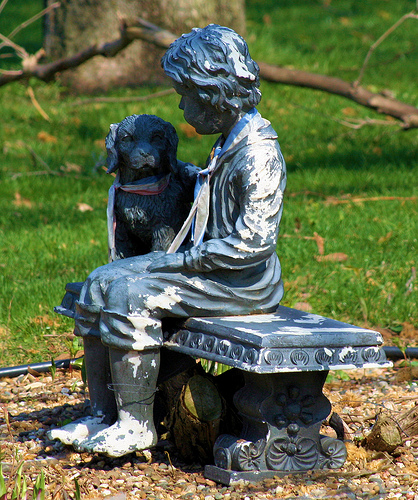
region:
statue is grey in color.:
[94, 81, 301, 306]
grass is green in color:
[296, 153, 357, 224]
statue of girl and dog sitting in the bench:
[106, 105, 280, 281]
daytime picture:
[56, 36, 361, 301]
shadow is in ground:
[300, 116, 378, 208]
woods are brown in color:
[48, 14, 148, 50]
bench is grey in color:
[241, 324, 268, 374]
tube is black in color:
[1, 353, 80, 391]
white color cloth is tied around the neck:
[84, 173, 218, 237]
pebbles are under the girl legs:
[93, 467, 151, 492]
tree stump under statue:
[156, 356, 243, 470]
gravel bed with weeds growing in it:
[0, 362, 416, 498]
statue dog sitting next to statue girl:
[99, 110, 196, 255]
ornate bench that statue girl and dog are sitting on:
[162, 309, 375, 482]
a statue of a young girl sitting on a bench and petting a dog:
[37, 23, 284, 455]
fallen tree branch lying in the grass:
[1, 14, 415, 150]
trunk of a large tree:
[44, 1, 253, 86]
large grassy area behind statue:
[3, 11, 414, 344]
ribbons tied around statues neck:
[168, 108, 265, 257]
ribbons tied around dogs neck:
[100, 181, 182, 259]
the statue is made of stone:
[120, 239, 288, 307]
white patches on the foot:
[94, 409, 172, 461]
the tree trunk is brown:
[168, 368, 232, 442]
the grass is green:
[333, 246, 410, 284]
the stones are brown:
[69, 468, 172, 483]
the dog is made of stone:
[100, 122, 180, 210]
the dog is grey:
[88, 118, 193, 226]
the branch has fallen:
[300, 45, 408, 101]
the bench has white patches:
[249, 312, 312, 329]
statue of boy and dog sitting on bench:
[42, 24, 390, 477]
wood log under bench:
[166, 360, 229, 455]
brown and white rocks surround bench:
[1, 352, 416, 498]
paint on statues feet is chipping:
[50, 406, 161, 461]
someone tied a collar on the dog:
[93, 111, 198, 253]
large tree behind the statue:
[36, 2, 276, 87]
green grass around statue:
[0, 38, 414, 350]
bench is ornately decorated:
[166, 305, 391, 484]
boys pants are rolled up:
[63, 295, 171, 355]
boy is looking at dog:
[97, 22, 271, 193]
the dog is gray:
[101, 110, 191, 254]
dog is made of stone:
[89, 105, 163, 238]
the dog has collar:
[95, 165, 194, 252]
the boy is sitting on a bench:
[141, 16, 287, 377]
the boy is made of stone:
[82, 13, 313, 386]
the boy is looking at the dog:
[61, 6, 337, 439]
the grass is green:
[305, 197, 410, 299]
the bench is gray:
[190, 310, 396, 481]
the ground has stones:
[26, 421, 119, 498]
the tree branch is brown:
[116, 6, 387, 151]